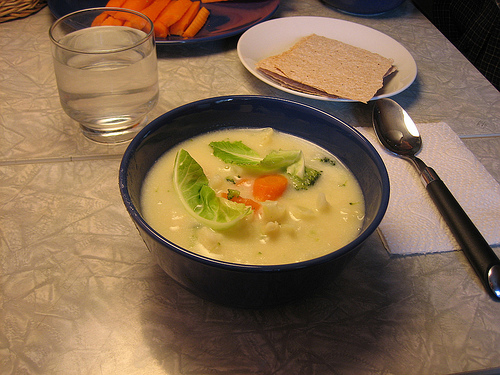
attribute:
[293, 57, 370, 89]
bread — hard, flat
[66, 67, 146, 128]
water — clear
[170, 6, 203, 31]
carrots — cut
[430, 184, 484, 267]
handle — black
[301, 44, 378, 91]
bread — hard, flat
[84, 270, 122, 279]
line — black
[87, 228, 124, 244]
line — black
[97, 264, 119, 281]
line — black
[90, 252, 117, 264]
line — black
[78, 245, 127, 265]
line — black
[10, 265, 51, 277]
line — black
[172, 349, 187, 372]
line — black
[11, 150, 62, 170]
line — black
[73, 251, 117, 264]
line — black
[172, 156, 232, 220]
lettuce — light green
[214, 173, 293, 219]
carrots — orange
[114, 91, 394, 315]
bowl — blue, glass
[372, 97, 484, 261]
spoon — silver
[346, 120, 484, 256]
napkin — white